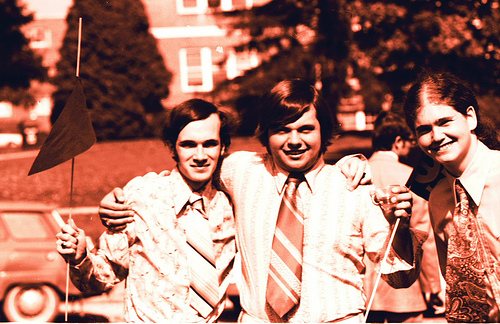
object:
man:
[53, 95, 236, 324]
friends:
[53, 72, 500, 317]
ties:
[258, 174, 315, 324]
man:
[216, 75, 412, 322]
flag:
[24, 37, 100, 319]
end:
[36, 194, 114, 304]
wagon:
[2, 195, 119, 324]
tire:
[3, 271, 66, 324]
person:
[361, 106, 413, 169]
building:
[151, 0, 267, 103]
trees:
[47, 1, 190, 141]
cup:
[368, 166, 408, 222]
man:
[398, 64, 499, 306]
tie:
[168, 184, 233, 319]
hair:
[161, 97, 220, 130]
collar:
[153, 166, 194, 216]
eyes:
[176, 138, 199, 149]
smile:
[274, 135, 315, 166]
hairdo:
[405, 65, 472, 106]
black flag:
[372, 152, 450, 273]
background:
[11, 14, 496, 170]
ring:
[387, 183, 413, 195]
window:
[172, 41, 220, 95]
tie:
[435, 178, 500, 324]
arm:
[86, 174, 156, 238]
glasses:
[402, 133, 422, 148]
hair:
[373, 113, 409, 149]